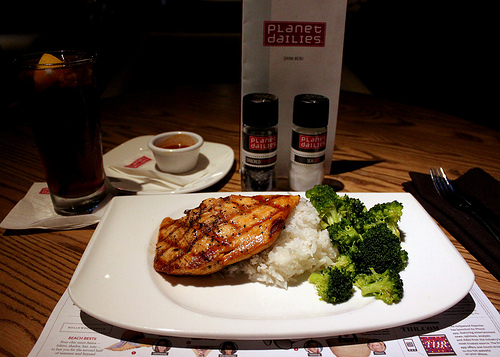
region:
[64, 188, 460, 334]
a dinner on a square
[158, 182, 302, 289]
chicken on top of rice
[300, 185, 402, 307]
rice and broccoli on plate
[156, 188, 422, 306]
chicken rice and broccoli on a plate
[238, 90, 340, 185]
salt and pepper shakers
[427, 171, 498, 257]
fork on a brown napkin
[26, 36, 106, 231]
Ice tea in a glass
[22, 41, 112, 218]
ice tea with a lemon in a glass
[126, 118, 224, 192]
sauce on a saucer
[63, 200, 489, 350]
plate sitting on a paper matt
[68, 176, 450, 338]
a square plate on a table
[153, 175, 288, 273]
chicken on a square plate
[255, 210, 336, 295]
rice on a square plate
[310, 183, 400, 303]
broccoli on a square plate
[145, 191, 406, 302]
chicken rice and broccoli on a square plate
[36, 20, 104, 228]
a glass on the table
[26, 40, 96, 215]
a glass of tea on the table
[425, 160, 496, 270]
a fork on a napkin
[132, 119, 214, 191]
sauce on a saucer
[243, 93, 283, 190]
A black pepper shaker.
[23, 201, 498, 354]
A placemat.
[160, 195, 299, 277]
a piece of grilled chicken.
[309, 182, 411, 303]
Green broccoli pieces.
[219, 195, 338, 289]
White rice.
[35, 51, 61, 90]
A yellow lemon wedge.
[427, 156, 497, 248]
A silver fork.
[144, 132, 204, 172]
A small white condiments cup.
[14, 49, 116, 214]
a glass of dark liquid.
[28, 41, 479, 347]
A meal is ready to eat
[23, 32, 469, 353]
A delicious meal is served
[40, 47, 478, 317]
A meal in a nice restaurant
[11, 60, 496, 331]
A meal made from scratch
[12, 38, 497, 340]
A dinner for a person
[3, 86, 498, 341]
A healthy meal with meat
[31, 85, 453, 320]
A meal served with broccoli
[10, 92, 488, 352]
The meal includes white rice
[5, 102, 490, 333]
The meal has barbecued chicken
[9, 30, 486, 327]
The meal is complete with soft drink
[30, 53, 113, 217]
soft drink in glass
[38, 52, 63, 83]
slice of lemon in glass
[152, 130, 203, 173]
white cup with sauce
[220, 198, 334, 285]
pile of white rice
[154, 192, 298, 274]
chicken with grill marks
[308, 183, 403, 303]
broccoli on white plate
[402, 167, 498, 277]
fork on brown napkin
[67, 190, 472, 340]
white plate of food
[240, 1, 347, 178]
white paper with red logo